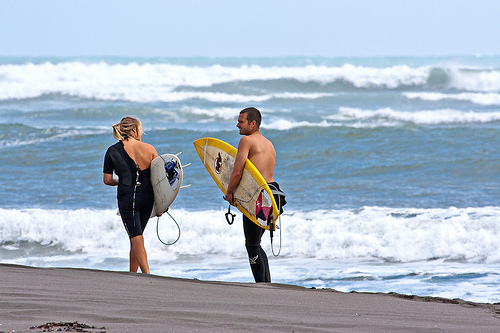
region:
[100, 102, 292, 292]
A man and a woman holding surfboards by the sea shore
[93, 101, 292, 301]
A man and a woman holding surfboards by the sea shore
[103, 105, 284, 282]
a man and a woman walking on the beach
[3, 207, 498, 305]
gentle wave washing on the beach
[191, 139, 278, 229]
a yellow surfboard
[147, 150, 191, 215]
woman carrying a white surfboard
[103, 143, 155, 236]
woman wearing a black wet suit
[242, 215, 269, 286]
man wearing black wet pants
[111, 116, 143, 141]
a blonde woman with a pony tail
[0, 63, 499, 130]
white foam on an ocean wave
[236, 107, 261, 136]
man with a buzz cut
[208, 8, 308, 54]
this is the sky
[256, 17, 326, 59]
the sky is blue in color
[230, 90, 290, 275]
this is a man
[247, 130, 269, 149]
the man is light skinned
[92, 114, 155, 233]
this is a lady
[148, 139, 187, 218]
this is a surfboard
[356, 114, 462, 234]
this is a water body